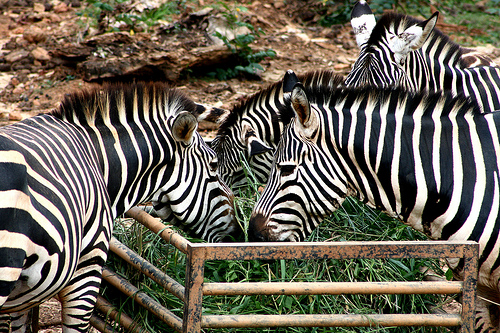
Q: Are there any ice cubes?
A: No, there are no ice cubes.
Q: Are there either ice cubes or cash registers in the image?
A: No, there are no ice cubes or cash registers.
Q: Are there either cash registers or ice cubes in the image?
A: No, there are no ice cubes or cash registers.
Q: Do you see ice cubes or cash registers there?
A: No, there are no ice cubes or cash registers.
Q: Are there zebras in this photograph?
A: Yes, there is a zebra.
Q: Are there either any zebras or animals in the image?
A: Yes, there is a zebra.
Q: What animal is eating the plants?
A: The zebra is eating the plants.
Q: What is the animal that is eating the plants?
A: The animal is a zebra.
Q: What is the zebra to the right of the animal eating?
A: The zebra is eating plants.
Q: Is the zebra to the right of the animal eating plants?
A: Yes, the zebra is eating plants.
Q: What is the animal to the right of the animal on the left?
A: The animal is a zebra.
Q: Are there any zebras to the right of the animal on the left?
A: Yes, there is a zebra to the right of the animal.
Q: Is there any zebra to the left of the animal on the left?
A: No, the zebra is to the right of the animal.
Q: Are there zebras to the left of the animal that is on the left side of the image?
A: No, the zebra is to the right of the animal.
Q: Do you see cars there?
A: No, there are no cars.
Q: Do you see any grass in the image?
A: Yes, there is grass.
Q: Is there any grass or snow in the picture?
A: Yes, there is grass.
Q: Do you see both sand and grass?
A: No, there is grass but no sand.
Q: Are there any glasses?
A: No, there are no glasses.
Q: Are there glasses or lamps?
A: No, there are no glasses or lamps.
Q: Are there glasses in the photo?
A: No, there are no glasses.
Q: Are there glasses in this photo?
A: No, there are no glasses.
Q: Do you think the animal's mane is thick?
A: Yes, the mane is thick.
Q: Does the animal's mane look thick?
A: Yes, the mane is thick.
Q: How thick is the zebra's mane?
A: The mane is thick.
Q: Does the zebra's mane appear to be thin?
A: No, the mane is thick.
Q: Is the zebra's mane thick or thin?
A: The mane is thick.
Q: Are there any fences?
A: Yes, there is a fence.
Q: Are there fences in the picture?
A: Yes, there is a fence.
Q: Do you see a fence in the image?
A: Yes, there is a fence.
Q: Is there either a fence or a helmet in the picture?
A: Yes, there is a fence.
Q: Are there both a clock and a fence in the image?
A: No, there is a fence but no clocks.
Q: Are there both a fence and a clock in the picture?
A: No, there is a fence but no clocks.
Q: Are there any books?
A: No, there are no books.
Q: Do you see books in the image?
A: No, there are no books.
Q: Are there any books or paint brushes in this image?
A: No, there are no books or paint brushes.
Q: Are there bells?
A: No, there are no bells.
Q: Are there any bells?
A: No, there are no bells.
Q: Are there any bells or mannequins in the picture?
A: No, there are no bells or mannequins.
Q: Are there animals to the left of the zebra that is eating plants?
A: Yes, there is an animal to the left of the zebra.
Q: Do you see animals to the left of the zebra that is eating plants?
A: Yes, there is an animal to the left of the zebra.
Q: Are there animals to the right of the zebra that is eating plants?
A: No, the animal is to the left of the zebra.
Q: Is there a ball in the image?
A: No, there are no balls.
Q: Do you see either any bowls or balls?
A: No, there are no balls or bowls.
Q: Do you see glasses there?
A: No, there are no glasses.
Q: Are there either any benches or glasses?
A: No, there are no glasses or benches.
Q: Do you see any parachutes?
A: No, there are no parachutes.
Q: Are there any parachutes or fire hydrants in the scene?
A: No, there are no parachutes or fire hydrants.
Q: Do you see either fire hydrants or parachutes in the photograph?
A: No, there are no parachutes or fire hydrants.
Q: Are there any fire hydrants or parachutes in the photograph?
A: No, there are no parachutes or fire hydrants.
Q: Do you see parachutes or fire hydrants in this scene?
A: No, there are no parachutes or fire hydrants.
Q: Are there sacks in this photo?
A: No, there are no sacks.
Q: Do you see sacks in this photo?
A: No, there are no sacks.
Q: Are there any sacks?
A: No, there are no sacks.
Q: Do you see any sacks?
A: No, there are no sacks.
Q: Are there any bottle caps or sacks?
A: No, there are no sacks or bottle caps.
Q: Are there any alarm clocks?
A: No, there are no alarm clocks.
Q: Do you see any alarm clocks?
A: No, there are no alarm clocks.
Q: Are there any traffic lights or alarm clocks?
A: No, there are no alarm clocks or traffic lights.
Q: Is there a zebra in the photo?
A: Yes, there is a zebra.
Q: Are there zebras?
A: Yes, there is a zebra.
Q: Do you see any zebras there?
A: Yes, there is a zebra.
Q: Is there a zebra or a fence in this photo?
A: Yes, there is a zebra.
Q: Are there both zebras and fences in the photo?
A: Yes, there are both a zebra and a fence.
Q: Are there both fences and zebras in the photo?
A: Yes, there are both a zebra and a fence.